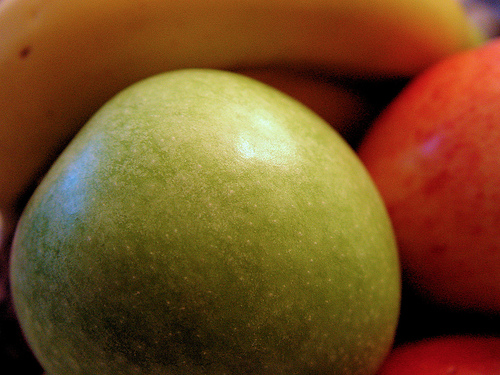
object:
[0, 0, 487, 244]
banana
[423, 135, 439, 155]
light shining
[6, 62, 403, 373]
apples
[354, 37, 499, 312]
apple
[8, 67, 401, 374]
apple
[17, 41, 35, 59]
black spot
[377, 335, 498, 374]
fruit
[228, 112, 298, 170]
light